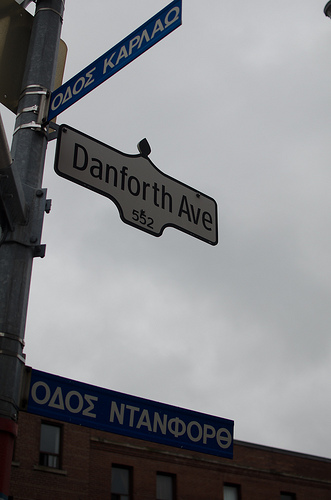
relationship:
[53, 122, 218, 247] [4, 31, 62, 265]
sign on pole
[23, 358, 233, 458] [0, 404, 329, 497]
sign on building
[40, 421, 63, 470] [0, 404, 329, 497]
window are on building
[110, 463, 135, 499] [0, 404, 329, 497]
window are on building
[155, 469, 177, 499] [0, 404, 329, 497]
window are on building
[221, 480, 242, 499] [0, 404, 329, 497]
window are on building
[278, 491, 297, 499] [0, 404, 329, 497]
window are on building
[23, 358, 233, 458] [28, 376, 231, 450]
sign in foreign language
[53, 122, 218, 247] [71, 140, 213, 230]
sign with letters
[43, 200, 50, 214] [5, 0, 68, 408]
bolt on a pole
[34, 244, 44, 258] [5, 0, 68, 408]
bolt on a pole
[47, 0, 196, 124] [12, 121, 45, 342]
blue sign on pole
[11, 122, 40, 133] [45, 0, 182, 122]
clasp hold blue sign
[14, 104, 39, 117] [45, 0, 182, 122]
clasp hold blue sign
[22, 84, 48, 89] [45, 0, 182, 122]
clasp hold blue sign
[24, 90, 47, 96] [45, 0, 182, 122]
clasp hold blue sign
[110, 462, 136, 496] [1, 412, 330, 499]
window on building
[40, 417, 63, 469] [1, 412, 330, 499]
window on building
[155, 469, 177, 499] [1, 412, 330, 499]
window on building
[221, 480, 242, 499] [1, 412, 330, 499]
window on building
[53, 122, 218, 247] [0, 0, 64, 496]
sign on pole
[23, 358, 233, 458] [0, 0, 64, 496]
sign on pole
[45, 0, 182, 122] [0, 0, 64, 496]
blue sign on pole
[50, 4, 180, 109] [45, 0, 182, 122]
letters on blue sign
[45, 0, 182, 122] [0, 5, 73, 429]
blue sign on pole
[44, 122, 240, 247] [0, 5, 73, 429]
sign on pole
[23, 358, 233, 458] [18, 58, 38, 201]
sign on pole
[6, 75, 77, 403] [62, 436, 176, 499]
pole on side of building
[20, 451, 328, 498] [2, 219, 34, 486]
building behind pole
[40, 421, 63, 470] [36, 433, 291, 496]
window of building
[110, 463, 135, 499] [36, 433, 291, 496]
window of building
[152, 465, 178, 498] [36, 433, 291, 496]
window of building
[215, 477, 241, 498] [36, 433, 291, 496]
window of building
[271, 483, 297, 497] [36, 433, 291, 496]
window of building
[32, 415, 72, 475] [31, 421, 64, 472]
balcony on window